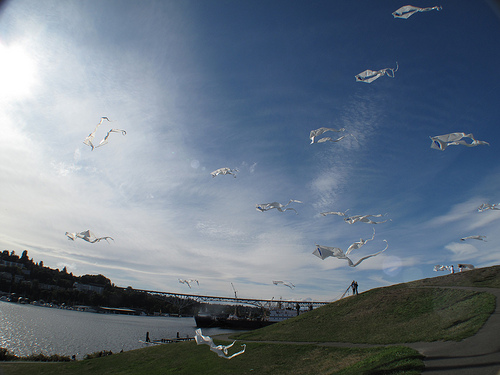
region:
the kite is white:
[305, 227, 379, 295]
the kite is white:
[320, 247, 365, 284]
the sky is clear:
[107, 77, 344, 301]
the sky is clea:
[131, 40, 333, 339]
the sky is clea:
[85, 39, 281, 274]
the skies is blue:
[255, 30, 300, 50]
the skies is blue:
[240, 35, 275, 50]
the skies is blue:
[235, 80, 305, 130]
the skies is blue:
[210, 100, 255, 155]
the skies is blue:
[200, 105, 280, 170]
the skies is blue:
[245, 40, 335, 80]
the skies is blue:
[250, 75, 400, 145]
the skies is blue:
[265, 105, 340, 160]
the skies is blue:
[267, 42, 317, 88]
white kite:
[193, 326, 247, 360]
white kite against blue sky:
[255, 197, 305, 214]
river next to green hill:
[1, 301, 243, 358]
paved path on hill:
[212, 279, 498, 370]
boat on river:
[194, 300, 272, 332]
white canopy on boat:
[199, 300, 261, 311]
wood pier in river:
[153, 334, 195, 343]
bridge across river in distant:
[143, 288, 324, 325]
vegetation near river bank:
[0, 345, 112, 360]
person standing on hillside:
[350, 279, 362, 294]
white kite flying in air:
[387, 2, 447, 32]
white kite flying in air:
[76, 106, 133, 156]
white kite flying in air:
[57, 222, 117, 250]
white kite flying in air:
[294, 117, 366, 157]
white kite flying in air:
[182, 324, 264, 359]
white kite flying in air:
[305, 235, 377, 275]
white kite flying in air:
[406, 115, 480, 161]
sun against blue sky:
[12, 13, 251, 104]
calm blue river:
[8, 303, 125, 346]